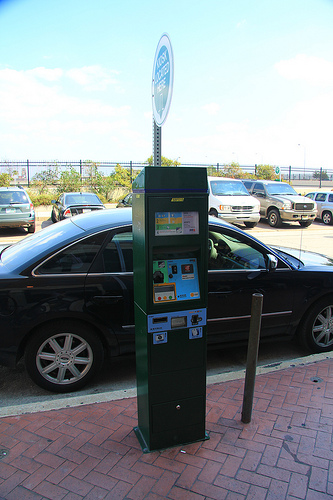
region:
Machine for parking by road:
[121, 152, 238, 451]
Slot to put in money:
[179, 304, 226, 364]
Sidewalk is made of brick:
[218, 428, 287, 497]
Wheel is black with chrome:
[26, 326, 117, 385]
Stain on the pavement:
[278, 427, 326, 499]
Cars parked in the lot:
[208, 166, 323, 220]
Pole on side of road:
[235, 278, 265, 431]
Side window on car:
[213, 223, 294, 280]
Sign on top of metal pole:
[147, 78, 172, 127]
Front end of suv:
[276, 194, 321, 226]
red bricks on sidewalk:
[0, 418, 116, 481]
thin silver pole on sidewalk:
[217, 295, 271, 449]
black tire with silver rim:
[8, 325, 100, 420]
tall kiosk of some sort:
[122, 162, 217, 467]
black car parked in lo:
[37, 186, 108, 232]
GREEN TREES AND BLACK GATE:
[0, 155, 90, 197]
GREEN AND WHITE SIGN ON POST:
[111, 31, 195, 167]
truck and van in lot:
[202, 170, 320, 238]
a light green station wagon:
[0, 166, 39, 252]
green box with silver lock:
[125, 388, 210, 446]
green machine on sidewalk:
[119, 159, 214, 458]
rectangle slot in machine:
[147, 313, 171, 328]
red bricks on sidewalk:
[208, 438, 281, 485]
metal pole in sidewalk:
[229, 285, 270, 428]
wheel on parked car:
[20, 310, 116, 397]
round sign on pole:
[143, 23, 183, 146]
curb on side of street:
[71, 385, 128, 412]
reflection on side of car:
[35, 281, 113, 324]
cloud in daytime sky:
[34, 83, 103, 141]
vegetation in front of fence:
[33, 158, 115, 189]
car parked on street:
[8, 188, 296, 388]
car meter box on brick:
[117, 185, 236, 428]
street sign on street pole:
[137, 31, 215, 173]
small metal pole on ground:
[219, 285, 280, 416]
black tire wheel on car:
[11, 315, 123, 379]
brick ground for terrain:
[79, 418, 255, 496]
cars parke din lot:
[13, 168, 312, 256]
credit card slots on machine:
[147, 261, 192, 314]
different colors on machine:
[95, 210, 203, 245]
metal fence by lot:
[3, 163, 277, 215]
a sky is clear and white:
[213, 31, 272, 112]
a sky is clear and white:
[235, 42, 280, 110]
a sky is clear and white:
[227, 43, 296, 149]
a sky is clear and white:
[218, 76, 268, 149]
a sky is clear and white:
[225, 58, 269, 122]